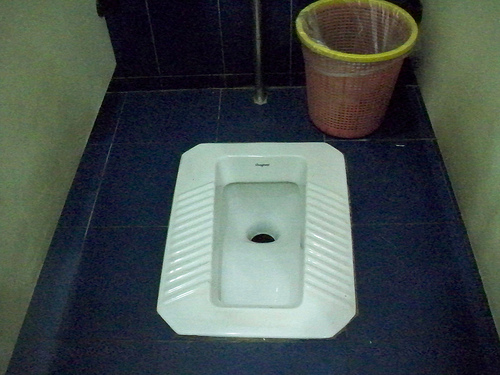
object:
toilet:
[157, 141, 356, 339]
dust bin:
[290, 0, 422, 144]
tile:
[123, 89, 219, 144]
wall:
[0, 0, 92, 131]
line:
[116, 91, 134, 105]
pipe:
[247, 2, 269, 105]